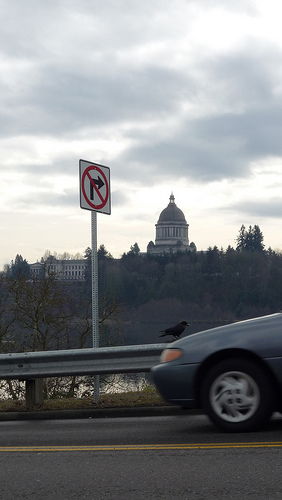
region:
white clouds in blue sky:
[11, 28, 58, 70]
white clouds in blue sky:
[118, 84, 162, 134]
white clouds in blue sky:
[193, 113, 246, 177]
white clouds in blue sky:
[8, 159, 43, 205]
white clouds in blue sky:
[94, 37, 144, 115]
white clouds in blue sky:
[193, 26, 254, 116]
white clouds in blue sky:
[141, 107, 176, 165]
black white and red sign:
[64, 152, 122, 223]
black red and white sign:
[68, 156, 115, 227]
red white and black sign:
[64, 148, 120, 220]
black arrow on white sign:
[87, 174, 103, 201]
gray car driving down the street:
[155, 303, 281, 422]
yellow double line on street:
[0, 438, 280, 454]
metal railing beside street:
[1, 343, 164, 404]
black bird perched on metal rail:
[157, 319, 187, 339]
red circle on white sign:
[80, 165, 106, 206]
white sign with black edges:
[76, 160, 114, 214]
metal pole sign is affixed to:
[87, 214, 102, 407]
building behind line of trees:
[24, 191, 269, 284]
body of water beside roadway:
[0, 319, 227, 392]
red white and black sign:
[77, 158, 111, 214]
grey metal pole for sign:
[92, 212, 98, 402]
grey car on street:
[153, 311, 281, 429]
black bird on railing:
[160, 320, 189, 340]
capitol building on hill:
[142, 190, 196, 256]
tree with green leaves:
[4, 260, 117, 397]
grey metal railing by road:
[1, 342, 170, 372]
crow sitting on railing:
[159, 318, 187, 339]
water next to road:
[0, 374, 156, 398]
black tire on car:
[202, 359, 275, 431]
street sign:
[69, 160, 108, 212]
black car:
[135, 297, 280, 419]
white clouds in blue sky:
[28, 80, 86, 148]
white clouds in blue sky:
[14, 132, 40, 178]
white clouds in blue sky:
[27, 203, 49, 232]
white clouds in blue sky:
[185, 149, 248, 190]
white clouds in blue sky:
[207, 165, 243, 214]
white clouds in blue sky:
[140, 16, 171, 70]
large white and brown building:
[149, 197, 188, 242]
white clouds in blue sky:
[11, 10, 64, 58]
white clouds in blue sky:
[92, 21, 150, 66]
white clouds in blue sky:
[172, 28, 209, 67]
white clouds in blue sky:
[167, 107, 233, 171]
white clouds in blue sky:
[27, 175, 60, 214]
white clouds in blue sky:
[77, 74, 141, 115]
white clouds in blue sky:
[139, 132, 195, 179]